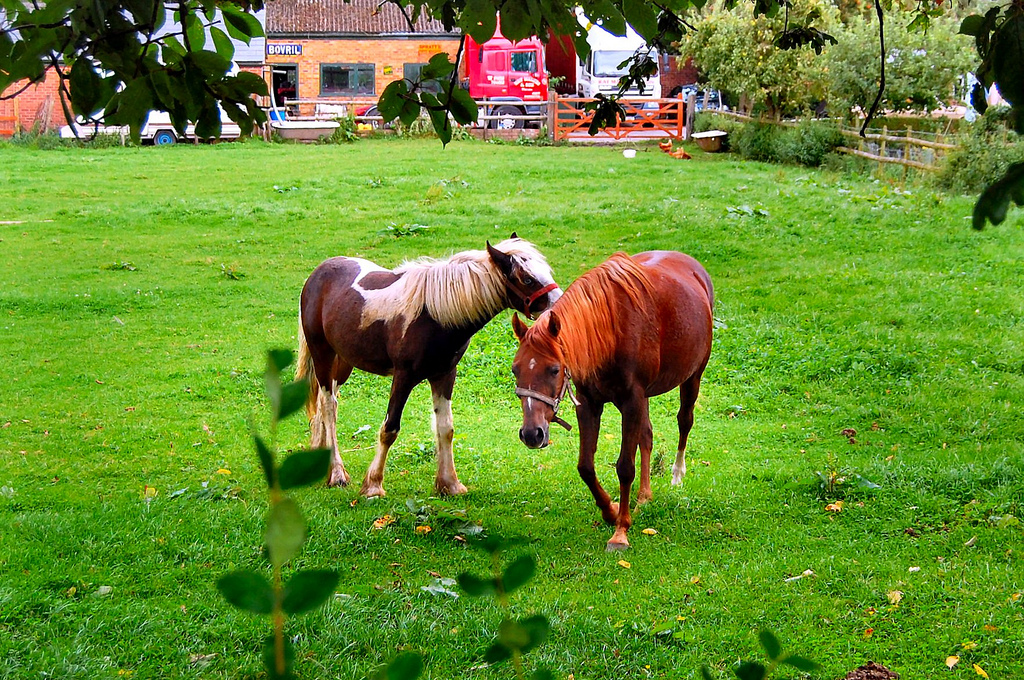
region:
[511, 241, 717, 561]
A brown, sleek horse with a bridle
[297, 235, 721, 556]
Two horses in a pasture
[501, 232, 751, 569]
brown horse with brown mane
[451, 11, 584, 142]
red semi truck cab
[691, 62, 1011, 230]
double rail wood fence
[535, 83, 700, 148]
orange metal gate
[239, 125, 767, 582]
green pasture area for horses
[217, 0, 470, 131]
brick building behind pasture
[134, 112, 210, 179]
blue wheel on trailer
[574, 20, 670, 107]
white truck behind gate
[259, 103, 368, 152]
old white bathtub in pasture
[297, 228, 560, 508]
brown horse with white spots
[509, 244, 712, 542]
erd horse with bridle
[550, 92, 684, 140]
bright red gate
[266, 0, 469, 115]
orange building with brown roof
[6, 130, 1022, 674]
bright green horse pasture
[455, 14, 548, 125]
red semi truck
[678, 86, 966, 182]
fence made out of wood rounds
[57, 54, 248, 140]
small white motorhome with blue rims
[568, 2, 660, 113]
large white semi truck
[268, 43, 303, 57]
blue sign on building that says bovril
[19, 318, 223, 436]
Grass is bright green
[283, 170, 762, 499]
Two horses next to each other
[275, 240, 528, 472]
A horse is brown and white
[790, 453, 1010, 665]
Flowers in the grass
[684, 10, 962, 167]
Trees in the background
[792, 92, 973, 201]
A wooden fence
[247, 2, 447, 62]
Roof of a building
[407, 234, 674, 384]
Manes on two horses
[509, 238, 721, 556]
dark red horse in pasture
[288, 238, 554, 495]
brown and white horse in pasture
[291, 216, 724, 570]
two horses grazing in a pasture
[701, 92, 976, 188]
wooden fence alongside pasture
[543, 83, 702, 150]
red cattle guard gate to pasture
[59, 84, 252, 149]
white vehicle with blue wheels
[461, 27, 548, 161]
red semi tractor trailer truck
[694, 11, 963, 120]
group of trees next to pasture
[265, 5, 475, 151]
red brick building in background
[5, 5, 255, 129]
leaves on the overhanging branch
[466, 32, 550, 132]
A RED truck is in the background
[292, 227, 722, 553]
spotted white and brown horse sniffing brown horse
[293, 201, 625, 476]
A dark brown horse has his nose on a red horse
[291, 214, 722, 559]
two horses stand on the grass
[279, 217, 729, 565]
two brown horses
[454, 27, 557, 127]
red truck in the background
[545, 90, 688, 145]
the red gate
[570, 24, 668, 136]
a white truck to the right of the red truck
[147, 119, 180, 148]
blue tire of a trailer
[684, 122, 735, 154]
water trough for the horses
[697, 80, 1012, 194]
a wooden fence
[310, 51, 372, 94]
The window next to the door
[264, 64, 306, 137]
front door of the building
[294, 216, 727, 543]
two horses standing next to each other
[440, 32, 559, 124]
a red truck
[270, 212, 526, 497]
a brown and white horse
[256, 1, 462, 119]
a tan building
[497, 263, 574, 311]
a red halter on the horse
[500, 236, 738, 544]
a brown horse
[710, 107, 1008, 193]
wooden fence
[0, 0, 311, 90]
leaves on a tree